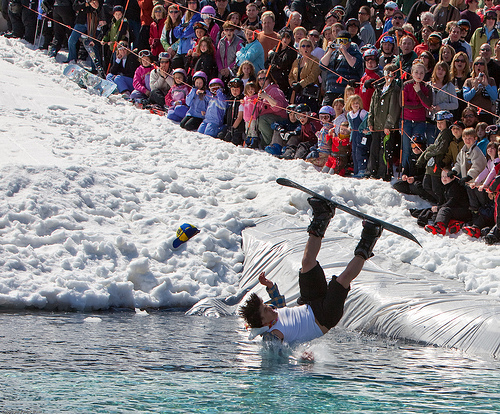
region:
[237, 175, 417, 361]
Snowboarder falls into water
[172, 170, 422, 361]
Snowboarder hat came off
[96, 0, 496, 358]
Audience watch as snowboarder falls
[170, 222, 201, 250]
Hat flying in the air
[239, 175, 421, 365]
Snowboarder lands in water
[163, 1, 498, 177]
Audience are shocked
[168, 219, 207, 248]
Blue and yellow cap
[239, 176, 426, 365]
Snowboarder is upside down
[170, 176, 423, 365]
Snowboarder hat flies off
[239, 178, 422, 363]
Snowboarder's feet are in the air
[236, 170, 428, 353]
A man on a snowboard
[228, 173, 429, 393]
A man falling into water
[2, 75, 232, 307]
Snow on the ground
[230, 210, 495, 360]
A white tarp over the snow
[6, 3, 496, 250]
A crowd in the background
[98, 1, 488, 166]
A crowd behind orange ropes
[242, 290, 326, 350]
A man wearing a white shirt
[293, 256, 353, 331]
A man wearing black shorts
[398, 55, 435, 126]
A girl in a maroon jacket watching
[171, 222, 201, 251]
A yellow and blue hat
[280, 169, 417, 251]
a snowboard in the air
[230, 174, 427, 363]
a snowboarder falling into the water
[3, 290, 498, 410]
ice cold water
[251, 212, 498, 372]
white tarp in the snow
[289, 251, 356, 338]
brown board shorts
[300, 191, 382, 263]
snowboard boots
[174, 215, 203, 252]
blue and yellow hat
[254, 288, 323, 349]
white tee shirt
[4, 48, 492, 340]
tracks in the white snow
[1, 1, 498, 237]
audience watching from the sidelines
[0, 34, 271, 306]
a snow-covered slope partially covered by rough snow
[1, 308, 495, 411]
a pool of water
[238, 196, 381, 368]
man falling into the water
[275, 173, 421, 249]
snowboard attached to man's elevated feet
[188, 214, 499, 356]
white plastic sheeting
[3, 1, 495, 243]
spectators behind flimsy rope barriers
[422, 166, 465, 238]
child sitting on the ground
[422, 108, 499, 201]
children leaning forward and gripping rope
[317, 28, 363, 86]
man holding a recording device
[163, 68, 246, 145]
children on their knees in the snow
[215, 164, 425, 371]
a snowboarder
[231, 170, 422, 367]
a man falling in the water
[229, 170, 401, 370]
the snowboarder is falling in the water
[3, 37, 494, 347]
a snow hill with water at the bottom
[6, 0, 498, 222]
a crowd watches the man on the snowboard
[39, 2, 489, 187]
a rope fence keeps the crowd back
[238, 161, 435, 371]
the man on the snowboard is wearing shorts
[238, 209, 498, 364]
plastic is along the water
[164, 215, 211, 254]
a hat is lying in the snow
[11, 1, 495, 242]
a large crowd is next to the hill